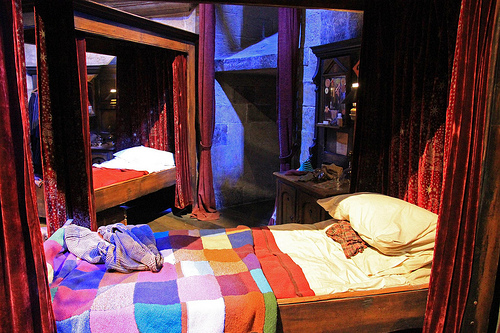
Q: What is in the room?
A: A bed.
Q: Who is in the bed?
A: Nobody.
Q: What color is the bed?
A: Brown.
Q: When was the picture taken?
A: Night time.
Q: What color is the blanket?
A: Rainbow.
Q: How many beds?
A: 2.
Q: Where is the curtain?
A: Around the bed.